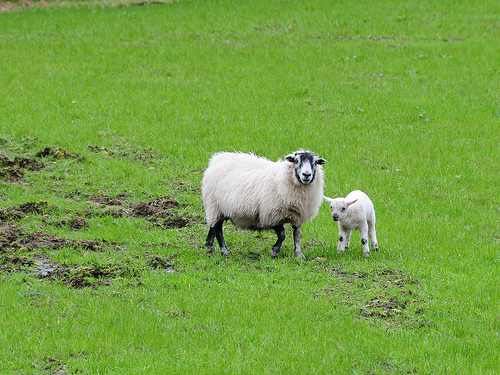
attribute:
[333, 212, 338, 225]
nose — black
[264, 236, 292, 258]
hooves — grey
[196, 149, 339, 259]
sheep — black, white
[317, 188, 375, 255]
lamb — white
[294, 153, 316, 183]
face — white, black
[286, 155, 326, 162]
ears — black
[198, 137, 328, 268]
sheep — mother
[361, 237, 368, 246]
patch — black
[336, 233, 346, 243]
patch — black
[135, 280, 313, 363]
grass — green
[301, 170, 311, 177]
nose — black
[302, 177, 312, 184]
mouth — black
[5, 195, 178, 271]
area — muddy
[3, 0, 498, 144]
grass — green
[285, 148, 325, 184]
sheep's face — white, black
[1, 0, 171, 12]
area — brown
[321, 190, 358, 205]
ears — white